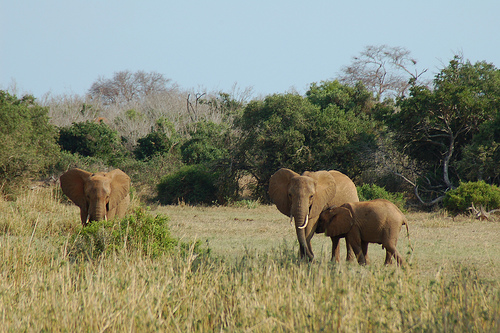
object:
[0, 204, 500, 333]
field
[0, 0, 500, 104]
sky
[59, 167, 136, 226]
elephant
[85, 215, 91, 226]
tusk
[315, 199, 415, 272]
elephant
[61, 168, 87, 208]
ear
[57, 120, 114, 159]
tree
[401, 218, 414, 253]
tail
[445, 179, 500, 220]
bush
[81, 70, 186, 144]
tree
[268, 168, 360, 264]
elephant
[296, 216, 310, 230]
tusk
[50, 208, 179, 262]
shrub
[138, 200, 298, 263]
opening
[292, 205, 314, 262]
trunk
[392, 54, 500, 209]
tree